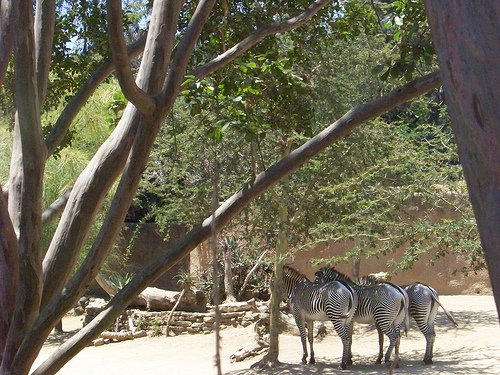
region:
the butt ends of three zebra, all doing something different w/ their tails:
[263, 260, 470, 372]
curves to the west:
[328, 279, 357, 326]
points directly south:
[399, 290, 412, 344]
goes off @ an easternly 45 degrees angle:
[425, 289, 465, 334]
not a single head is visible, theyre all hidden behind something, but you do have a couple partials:
[268, 262, 371, 304]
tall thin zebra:
[258, 262, 370, 370]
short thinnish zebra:
[376, 279, 463, 373]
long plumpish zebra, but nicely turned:
[306, 260, 416, 372]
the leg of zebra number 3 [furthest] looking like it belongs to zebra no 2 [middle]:
[368, 326, 387, 373]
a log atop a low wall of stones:
[69, 277, 256, 350]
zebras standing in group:
[275, 268, 437, 348]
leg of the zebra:
[292, 326, 309, 368]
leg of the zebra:
[308, 334, 318, 364]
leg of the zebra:
[336, 338, 348, 368]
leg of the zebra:
[374, 335, 381, 365]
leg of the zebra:
[417, 335, 436, 360]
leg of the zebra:
[390, 343, 403, 366]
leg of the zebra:
[370, 338, 382, 360]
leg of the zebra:
[342, 350, 354, 360]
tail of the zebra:
[437, 305, 470, 330]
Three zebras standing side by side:
[251, 248, 466, 374]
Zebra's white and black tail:
[426, 285, 474, 330]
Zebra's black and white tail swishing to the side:
[329, 289, 361, 324]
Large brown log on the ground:
[95, 273, 211, 317]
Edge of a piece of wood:
[415, 1, 499, 318]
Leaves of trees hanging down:
[0, 0, 437, 150]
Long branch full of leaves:
[118, 205, 169, 276]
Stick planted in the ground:
[162, 278, 192, 335]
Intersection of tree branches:
[117, 44, 193, 144]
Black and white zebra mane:
[320, 263, 359, 288]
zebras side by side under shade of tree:
[240, 222, 465, 370]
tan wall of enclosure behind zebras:
[187, 191, 487, 296]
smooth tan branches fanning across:
[2, 5, 428, 365]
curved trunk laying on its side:
[90, 255, 205, 305]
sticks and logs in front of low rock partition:
[86, 285, 207, 340]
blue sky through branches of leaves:
[42, 0, 357, 50]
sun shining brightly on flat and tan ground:
[60, 306, 291, 366]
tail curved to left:
[330, 275, 357, 325]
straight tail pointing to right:
[417, 280, 458, 330]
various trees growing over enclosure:
[6, 7, 466, 227]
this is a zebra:
[277, 267, 339, 374]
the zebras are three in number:
[281, 259, 435, 342]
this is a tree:
[336, 163, 403, 248]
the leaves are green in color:
[230, 48, 305, 103]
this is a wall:
[126, 224, 158, 253]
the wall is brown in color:
[411, 253, 451, 276]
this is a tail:
[427, 290, 466, 332]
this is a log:
[147, 288, 208, 309]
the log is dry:
[146, 292, 173, 305]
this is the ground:
[450, 338, 495, 370]